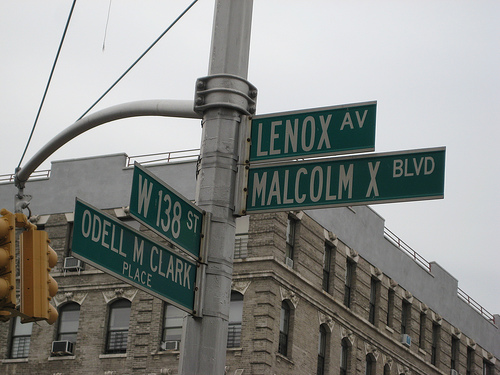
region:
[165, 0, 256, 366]
a gray metal post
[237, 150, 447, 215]
a green and white sign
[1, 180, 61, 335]
a yellow stop light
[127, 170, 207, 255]
a sign with numbers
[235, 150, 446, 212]
a sign with writing on it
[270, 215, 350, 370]
window in a building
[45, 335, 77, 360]
a air condition unit in a window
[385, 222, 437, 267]
metal bars on a roof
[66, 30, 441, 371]
signs on a gray pole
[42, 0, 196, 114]
a silver cable on a pole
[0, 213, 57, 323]
A traffic light near the building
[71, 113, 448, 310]
Street signs on the post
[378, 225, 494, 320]
A fence on the roof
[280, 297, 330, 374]
Windows on the building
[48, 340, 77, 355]
An air conditioning unit outside the window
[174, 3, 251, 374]
A silver post holding the street signs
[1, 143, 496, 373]
A building behind the street signs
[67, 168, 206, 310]
The street signs are green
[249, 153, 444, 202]
A street sign for Malcolm X Boulevard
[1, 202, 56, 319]
The traffic light is yellow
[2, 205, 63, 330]
the traffic signal is yellow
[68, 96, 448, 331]
directional signs are on a steel pole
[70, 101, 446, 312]
the signs are green with white lettering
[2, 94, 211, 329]
the signal light is hanging from a steel pole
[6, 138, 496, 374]
a building is at the intersection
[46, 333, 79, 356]
an air conditioner is in a window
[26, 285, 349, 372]
the windows on the building are arched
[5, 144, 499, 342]
the top of the building has a steel rail fence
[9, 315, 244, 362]
bars are on the windows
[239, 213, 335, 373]
the building is gray stone with parapets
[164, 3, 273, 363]
Pole with many street signs.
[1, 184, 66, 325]
Yellow street light in the city.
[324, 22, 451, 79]
Pale blue sky in the distance.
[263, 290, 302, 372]
Building with window arches.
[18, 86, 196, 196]
Arm that supports the street light.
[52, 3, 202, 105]
Electric wires over head.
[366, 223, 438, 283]
Railings to protect someone on the roof.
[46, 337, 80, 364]
Air conditioner in a window.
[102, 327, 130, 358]
Bars on a apartment window.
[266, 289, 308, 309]
Ornate concrete above a window.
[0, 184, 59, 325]
the traffic light hanging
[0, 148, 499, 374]
the large building behind the street signs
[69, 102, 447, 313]
the street signs on the pole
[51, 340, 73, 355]
the air conditioner unit in the window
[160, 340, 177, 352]
the air conditioner unit in the window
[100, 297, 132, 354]
the window on the building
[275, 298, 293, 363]
the window on the building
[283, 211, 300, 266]
the window on the building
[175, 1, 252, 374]
the pole for the street signs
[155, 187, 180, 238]
the numbers 138 on the sign